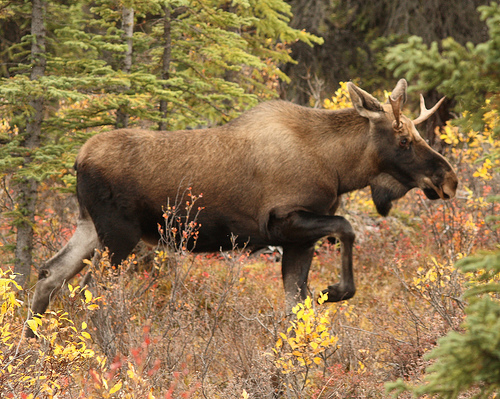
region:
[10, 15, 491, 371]
moose in wooded area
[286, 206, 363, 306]
joints bent on leg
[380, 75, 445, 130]
horns curving upwards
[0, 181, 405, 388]
yellow and red leaves among bare branches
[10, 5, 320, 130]
horizontal branches on evergreens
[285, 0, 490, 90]
darker area in back of forest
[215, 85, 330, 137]
hump on shoulder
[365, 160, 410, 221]
triangular piece of skin under neck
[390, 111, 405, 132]
circle at base of horn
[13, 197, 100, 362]
bent and gray rear leg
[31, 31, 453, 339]
a running moose in the forest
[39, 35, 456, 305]
this moose is in action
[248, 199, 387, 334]
the moose's leg is bent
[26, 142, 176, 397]
the moose's hind legs are moving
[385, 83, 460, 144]
horns on the moose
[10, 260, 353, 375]
yellow plants near the moose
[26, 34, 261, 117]
green pine trees near the moose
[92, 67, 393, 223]
the moose is brown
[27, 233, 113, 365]
this part of the moose is white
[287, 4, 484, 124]
the tree branch is brown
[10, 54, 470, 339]
the elk is brown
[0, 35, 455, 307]
the elk is in motion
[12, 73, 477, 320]
the animal is in motion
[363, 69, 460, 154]
the elk has antlers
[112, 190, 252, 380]
the branches are losing leaves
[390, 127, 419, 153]
the eye is open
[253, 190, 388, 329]
the leg is up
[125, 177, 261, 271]
the fur on the stomach is dark brown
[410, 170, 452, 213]
the mouth is closed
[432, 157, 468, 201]
the nose is brown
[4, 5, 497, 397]
Moose walking through a forest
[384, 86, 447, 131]
Small moose antlers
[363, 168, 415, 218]
Bell hanging from moose's throat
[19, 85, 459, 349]
Large moose with brown fur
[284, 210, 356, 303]
Moose's raised foreleg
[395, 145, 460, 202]
Muzzle on a moose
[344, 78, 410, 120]
Two upright ears on a moose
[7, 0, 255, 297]
Three pine trees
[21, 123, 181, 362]
Hindquarters of a moose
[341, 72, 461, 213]
Head of a moose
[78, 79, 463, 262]
brown moose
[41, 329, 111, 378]
short green and brown grass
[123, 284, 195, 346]
short green and brown grass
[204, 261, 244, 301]
short green and brown grass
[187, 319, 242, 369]
short green and brown grass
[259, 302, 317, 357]
short green and brown grass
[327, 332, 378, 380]
short green and brown grass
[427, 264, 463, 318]
short green and brown grass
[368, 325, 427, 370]
short green and brown grass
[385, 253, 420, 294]
short green and brown grass